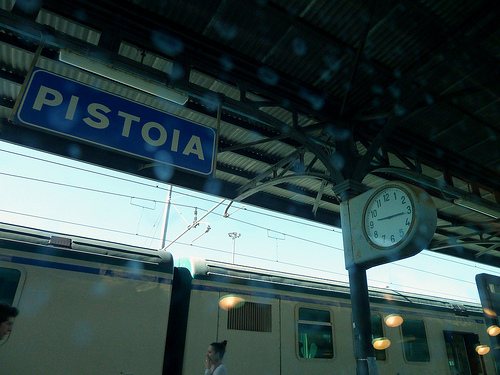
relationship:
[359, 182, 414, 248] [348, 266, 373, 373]
clock on pole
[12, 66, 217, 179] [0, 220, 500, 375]
sign hanging above subway train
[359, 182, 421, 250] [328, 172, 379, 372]
clock mounted to pole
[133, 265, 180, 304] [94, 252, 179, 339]
line painted on wall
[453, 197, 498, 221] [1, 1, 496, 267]
light mounted to ceiling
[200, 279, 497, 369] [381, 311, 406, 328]
reflection of round light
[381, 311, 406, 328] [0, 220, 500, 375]
light on subway train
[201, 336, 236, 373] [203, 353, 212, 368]
woman with hand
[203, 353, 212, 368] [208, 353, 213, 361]
hand over mouth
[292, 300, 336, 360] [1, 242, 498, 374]
window on side of train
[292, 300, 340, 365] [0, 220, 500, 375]
window on subway train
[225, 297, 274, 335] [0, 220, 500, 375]
vent on subway train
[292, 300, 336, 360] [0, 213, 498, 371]
window on subway train